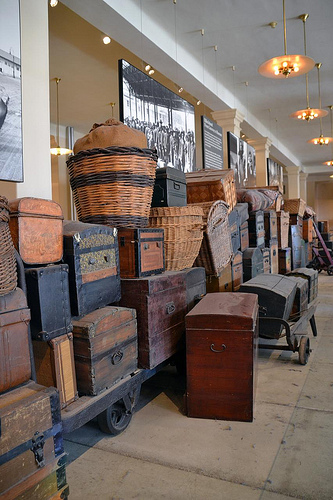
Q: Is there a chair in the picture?
A: No, there are no chairs.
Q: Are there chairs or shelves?
A: No, there are no chairs or shelves.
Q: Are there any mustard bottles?
A: No, there are no mustard bottles.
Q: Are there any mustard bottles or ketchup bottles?
A: No, there are no mustard bottles or ketchup bottles.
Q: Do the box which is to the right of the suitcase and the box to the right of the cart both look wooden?
A: Yes, both the box and the box are wooden.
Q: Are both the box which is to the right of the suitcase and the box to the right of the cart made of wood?
A: Yes, both the box and the box are made of wood.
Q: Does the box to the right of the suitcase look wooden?
A: Yes, the box is wooden.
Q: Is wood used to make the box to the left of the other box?
A: Yes, the box is made of wood.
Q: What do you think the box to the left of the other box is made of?
A: The box is made of wood.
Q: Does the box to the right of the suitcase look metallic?
A: No, the box is wooden.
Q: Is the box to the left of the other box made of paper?
A: No, the box is made of wood.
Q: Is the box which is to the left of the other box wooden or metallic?
A: The box is wooden.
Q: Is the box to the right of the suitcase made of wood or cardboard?
A: The box is made of wood.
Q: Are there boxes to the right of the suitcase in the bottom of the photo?
A: Yes, there is a box to the right of the suitcase.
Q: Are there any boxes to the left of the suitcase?
A: No, the box is to the right of the suitcase.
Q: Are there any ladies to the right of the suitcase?
A: No, there is a box to the right of the suitcase.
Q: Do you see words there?
A: Yes, there are words.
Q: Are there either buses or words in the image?
A: Yes, there are words.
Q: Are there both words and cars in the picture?
A: No, there are words but no cars.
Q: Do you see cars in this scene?
A: No, there are no cars.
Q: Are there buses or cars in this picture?
A: No, there are no cars or buses.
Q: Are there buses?
A: No, there are no buses.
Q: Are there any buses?
A: No, there are no buses.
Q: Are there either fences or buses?
A: No, there are no buses or fences.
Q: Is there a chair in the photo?
A: No, there are no chairs.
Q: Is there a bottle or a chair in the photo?
A: No, there are no chairs or bottles.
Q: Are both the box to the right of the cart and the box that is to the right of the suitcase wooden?
A: Yes, both the box and the box are wooden.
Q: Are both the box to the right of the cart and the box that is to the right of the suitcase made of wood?
A: Yes, both the box and the box are made of wood.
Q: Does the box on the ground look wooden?
A: Yes, the box is wooden.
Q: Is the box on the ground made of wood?
A: Yes, the box is made of wood.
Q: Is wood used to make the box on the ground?
A: Yes, the box is made of wood.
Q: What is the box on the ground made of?
A: The box is made of wood.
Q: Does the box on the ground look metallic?
A: No, the box is wooden.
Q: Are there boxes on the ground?
A: Yes, there is a box on the ground.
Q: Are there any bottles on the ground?
A: No, there is a box on the ground.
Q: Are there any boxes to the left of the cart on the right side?
A: Yes, there is a box to the left of the cart.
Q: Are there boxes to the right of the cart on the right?
A: No, the box is to the left of the cart.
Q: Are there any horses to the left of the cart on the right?
A: No, there is a box to the left of the cart.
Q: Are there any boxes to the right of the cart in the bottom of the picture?
A: Yes, there is a box to the right of the cart.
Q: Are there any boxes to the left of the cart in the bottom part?
A: No, the box is to the right of the cart.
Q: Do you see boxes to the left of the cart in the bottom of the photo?
A: No, the box is to the right of the cart.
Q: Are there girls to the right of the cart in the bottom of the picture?
A: No, there is a box to the right of the cart.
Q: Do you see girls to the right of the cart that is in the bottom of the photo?
A: No, there is a box to the right of the cart.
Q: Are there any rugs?
A: No, there are no rugs.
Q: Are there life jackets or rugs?
A: No, there are no rugs or life jackets.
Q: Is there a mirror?
A: No, there are no mirrors.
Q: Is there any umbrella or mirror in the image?
A: No, there are no mirrors or umbrellas.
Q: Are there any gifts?
A: No, there are no gifts.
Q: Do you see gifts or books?
A: No, there are no gifts or books.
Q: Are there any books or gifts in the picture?
A: No, there are no gifts or books.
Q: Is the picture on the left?
A: Yes, the picture is on the left of the image.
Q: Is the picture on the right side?
A: No, the picture is on the left of the image.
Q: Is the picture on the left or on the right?
A: The picture is on the left of the image.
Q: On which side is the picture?
A: The picture is on the left of the image.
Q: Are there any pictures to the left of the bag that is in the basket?
A: Yes, there is a picture to the left of the bag.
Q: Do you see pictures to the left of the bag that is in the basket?
A: Yes, there is a picture to the left of the bag.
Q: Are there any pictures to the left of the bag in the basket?
A: Yes, there is a picture to the left of the bag.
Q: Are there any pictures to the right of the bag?
A: No, the picture is to the left of the bag.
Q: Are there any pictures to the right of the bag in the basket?
A: No, the picture is to the left of the bag.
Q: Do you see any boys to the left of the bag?
A: No, there is a picture to the left of the bag.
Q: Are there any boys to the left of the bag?
A: No, there is a picture to the left of the bag.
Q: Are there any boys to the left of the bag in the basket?
A: No, there is a picture to the left of the bag.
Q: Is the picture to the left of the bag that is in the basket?
A: Yes, the picture is to the left of the bag.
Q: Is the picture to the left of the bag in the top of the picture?
A: Yes, the picture is to the left of the bag.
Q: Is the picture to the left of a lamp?
A: No, the picture is to the left of the bag.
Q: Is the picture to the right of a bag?
A: No, the picture is to the left of a bag.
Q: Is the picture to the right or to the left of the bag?
A: The picture is to the left of the bag.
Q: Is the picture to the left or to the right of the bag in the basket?
A: The picture is to the left of the bag.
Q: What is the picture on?
A: The picture is on the wall.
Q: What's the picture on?
A: The picture is on the wall.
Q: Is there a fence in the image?
A: No, there are no fences.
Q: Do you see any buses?
A: No, there are no buses.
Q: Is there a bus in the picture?
A: No, there are no buses.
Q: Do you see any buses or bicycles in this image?
A: No, there are no buses or bicycles.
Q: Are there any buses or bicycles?
A: No, there are no buses or bicycles.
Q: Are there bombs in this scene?
A: No, there are no bombs.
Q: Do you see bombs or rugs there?
A: No, there are no bombs or rugs.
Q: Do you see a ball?
A: No, there are no balls.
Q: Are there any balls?
A: No, there are no balls.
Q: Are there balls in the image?
A: No, there are no balls.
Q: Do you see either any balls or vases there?
A: No, there are no balls or vases.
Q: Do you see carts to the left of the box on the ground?
A: Yes, there is a cart to the left of the box.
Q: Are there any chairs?
A: No, there are no chairs.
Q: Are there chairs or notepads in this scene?
A: No, there are no chairs or notepads.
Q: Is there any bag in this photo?
A: Yes, there is a bag.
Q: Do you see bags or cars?
A: Yes, there is a bag.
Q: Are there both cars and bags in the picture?
A: No, there is a bag but no cars.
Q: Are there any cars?
A: No, there are no cars.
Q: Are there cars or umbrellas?
A: No, there are no cars or umbrellas.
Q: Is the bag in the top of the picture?
A: Yes, the bag is in the top of the image.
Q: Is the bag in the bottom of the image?
A: No, the bag is in the top of the image.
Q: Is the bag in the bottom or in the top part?
A: The bag is in the top of the image.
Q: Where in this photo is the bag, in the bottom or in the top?
A: The bag is in the top of the image.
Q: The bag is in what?
A: The bag is in the basket.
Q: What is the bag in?
A: The bag is in the basket.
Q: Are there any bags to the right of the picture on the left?
A: Yes, there is a bag to the right of the picture.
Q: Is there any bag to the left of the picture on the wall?
A: No, the bag is to the right of the picture.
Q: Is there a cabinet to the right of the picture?
A: No, there is a bag to the right of the picture.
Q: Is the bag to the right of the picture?
A: Yes, the bag is to the right of the picture.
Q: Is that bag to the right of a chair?
A: No, the bag is to the right of the picture.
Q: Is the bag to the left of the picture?
A: No, the bag is to the right of the picture.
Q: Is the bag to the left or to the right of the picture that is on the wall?
A: The bag is to the right of the picture.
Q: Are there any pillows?
A: No, there are no pillows.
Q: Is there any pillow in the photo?
A: No, there are no pillows.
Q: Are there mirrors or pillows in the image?
A: No, there are no pillows or mirrors.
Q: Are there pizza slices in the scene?
A: No, there are no pizza slices.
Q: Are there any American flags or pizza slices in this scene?
A: No, there are no pizza slices or American flags.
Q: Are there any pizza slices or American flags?
A: No, there are no pizza slices or American flags.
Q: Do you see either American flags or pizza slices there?
A: No, there are no pizza slices or American flags.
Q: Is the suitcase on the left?
A: Yes, the suitcase is on the left of the image.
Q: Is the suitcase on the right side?
A: No, the suitcase is on the left of the image.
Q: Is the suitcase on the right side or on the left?
A: The suitcase is on the left of the image.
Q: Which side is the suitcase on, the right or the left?
A: The suitcase is on the left of the image.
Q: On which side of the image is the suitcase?
A: The suitcase is on the left of the image.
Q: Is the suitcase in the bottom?
A: Yes, the suitcase is in the bottom of the image.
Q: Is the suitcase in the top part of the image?
A: No, the suitcase is in the bottom of the image.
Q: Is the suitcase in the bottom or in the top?
A: The suitcase is in the bottom of the image.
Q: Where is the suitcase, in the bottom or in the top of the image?
A: The suitcase is in the bottom of the image.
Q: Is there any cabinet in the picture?
A: No, there are no cabinets.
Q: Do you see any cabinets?
A: No, there are no cabinets.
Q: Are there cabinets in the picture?
A: No, there are no cabinets.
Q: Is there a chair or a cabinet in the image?
A: No, there are no cabinets or chairs.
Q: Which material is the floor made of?
A: The floor is made of concrete.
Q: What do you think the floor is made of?
A: The floor is made of concrete.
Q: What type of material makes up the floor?
A: The floor is made of concrete.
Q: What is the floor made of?
A: The floor is made of concrete.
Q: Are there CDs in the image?
A: No, there are no cds.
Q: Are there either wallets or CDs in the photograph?
A: No, there are no CDs or wallets.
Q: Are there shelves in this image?
A: No, there are no shelves.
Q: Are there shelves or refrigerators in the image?
A: No, there are no shelves or refrigerators.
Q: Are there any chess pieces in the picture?
A: No, there are no chess pieces.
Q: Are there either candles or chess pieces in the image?
A: No, there are no chess pieces or candles.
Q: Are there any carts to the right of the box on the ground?
A: Yes, there is a cart to the right of the box.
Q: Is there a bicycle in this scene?
A: No, there are no bicycles.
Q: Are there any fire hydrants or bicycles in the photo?
A: No, there are no bicycles or fire hydrants.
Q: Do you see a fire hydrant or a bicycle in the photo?
A: No, there are no bicycles or fire hydrants.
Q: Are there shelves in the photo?
A: No, there are no shelves.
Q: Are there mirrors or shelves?
A: No, there are no shelves or mirrors.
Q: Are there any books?
A: No, there are no books.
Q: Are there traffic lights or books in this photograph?
A: No, there are no books or traffic lights.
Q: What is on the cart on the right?
A: The trunk is on the cart.